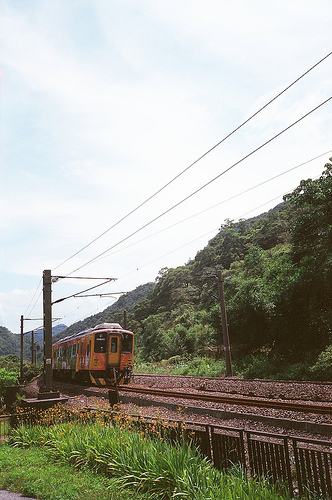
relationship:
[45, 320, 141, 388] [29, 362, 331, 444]
train on track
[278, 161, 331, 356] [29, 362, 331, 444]
tree alongside track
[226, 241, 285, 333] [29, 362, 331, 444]
tree alongside track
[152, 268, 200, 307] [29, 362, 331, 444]
tree alongside track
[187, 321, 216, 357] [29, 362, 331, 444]
tree alongside track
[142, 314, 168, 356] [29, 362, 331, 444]
tree alongside track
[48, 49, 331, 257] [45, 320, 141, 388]
wire above train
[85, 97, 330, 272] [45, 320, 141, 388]
wire above train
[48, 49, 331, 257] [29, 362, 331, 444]
wire above track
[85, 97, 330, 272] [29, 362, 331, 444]
wire above track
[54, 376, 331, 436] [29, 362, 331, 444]
gravel near track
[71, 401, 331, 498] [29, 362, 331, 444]
gate alongside track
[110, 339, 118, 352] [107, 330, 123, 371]
person standing at door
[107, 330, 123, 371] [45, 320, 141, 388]
door of train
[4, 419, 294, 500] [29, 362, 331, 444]
grass next to track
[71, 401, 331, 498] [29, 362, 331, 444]
gate next to track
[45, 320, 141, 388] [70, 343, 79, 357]
train has window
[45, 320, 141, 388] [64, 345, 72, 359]
train has window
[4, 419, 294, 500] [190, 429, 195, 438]
grass has flower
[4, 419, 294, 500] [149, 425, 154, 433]
grass has flower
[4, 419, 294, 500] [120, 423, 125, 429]
grass has flower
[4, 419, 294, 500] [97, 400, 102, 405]
grass has flower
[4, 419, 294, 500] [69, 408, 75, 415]
grass has flower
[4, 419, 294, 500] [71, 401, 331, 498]
grass near gate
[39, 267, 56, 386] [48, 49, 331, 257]
telephone post attached to wire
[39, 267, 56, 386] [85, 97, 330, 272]
telephone post attached to wire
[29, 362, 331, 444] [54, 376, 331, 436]
track on gravel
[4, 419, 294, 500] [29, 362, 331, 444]
grass on side of track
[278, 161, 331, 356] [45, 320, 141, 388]
tree near train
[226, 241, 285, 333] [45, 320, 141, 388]
tree near train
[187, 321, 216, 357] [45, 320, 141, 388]
tree near train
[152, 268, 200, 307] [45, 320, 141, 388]
tree near train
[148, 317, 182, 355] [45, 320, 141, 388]
tree near train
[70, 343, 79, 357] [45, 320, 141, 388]
window on train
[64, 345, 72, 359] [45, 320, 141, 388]
window on train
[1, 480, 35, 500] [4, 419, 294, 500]
cement on side of grass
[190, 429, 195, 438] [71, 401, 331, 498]
flower growing near gate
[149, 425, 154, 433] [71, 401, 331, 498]
flower growing near gate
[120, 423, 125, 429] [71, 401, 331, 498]
flower growing near gate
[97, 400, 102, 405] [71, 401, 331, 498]
flower growing near gate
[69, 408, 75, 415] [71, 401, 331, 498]
flower growing near gate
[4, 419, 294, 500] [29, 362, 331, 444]
grass near track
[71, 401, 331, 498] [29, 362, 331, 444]
gate beside track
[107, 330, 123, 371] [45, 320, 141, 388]
door on front of train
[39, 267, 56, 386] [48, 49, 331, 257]
telephone post has wire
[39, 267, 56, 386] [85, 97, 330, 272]
telephone post has wire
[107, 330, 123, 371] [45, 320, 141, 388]
door on train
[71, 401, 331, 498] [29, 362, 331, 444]
gate along side track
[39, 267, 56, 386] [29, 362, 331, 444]
telephone post along side of track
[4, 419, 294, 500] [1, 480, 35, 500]
grass along cement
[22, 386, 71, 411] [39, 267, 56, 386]
base of telephone post